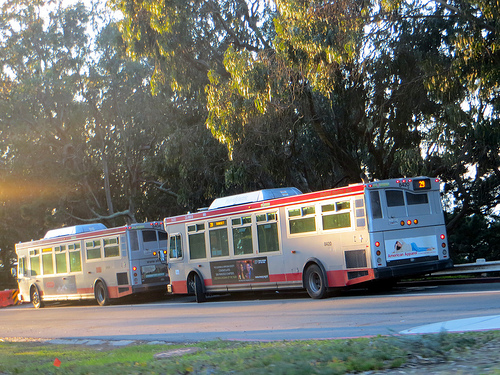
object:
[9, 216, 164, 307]
bus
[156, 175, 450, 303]
bus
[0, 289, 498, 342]
road